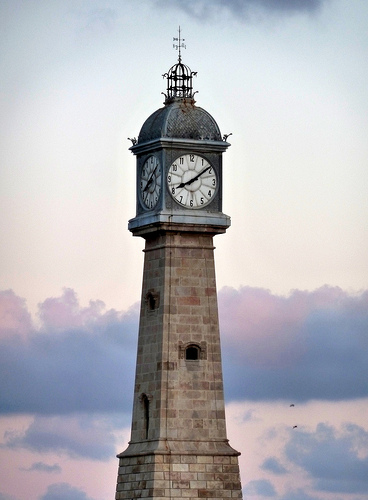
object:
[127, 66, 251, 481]
tower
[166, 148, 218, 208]
clock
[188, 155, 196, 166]
numerals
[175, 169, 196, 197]
hand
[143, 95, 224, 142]
roof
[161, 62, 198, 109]
ornament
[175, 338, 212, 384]
window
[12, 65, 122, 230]
sky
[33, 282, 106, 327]
clouds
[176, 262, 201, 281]
brick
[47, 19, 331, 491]
photo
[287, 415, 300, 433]
birds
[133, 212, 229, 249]
base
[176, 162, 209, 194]
face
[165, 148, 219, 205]
time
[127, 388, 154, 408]
archway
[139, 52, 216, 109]
weather vane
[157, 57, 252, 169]
bell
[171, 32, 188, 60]
cross